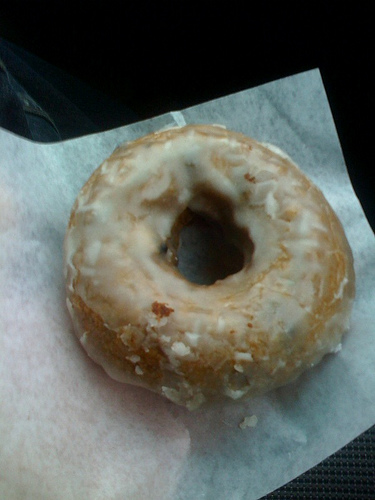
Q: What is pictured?
A: A donut.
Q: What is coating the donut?
A: Frosting.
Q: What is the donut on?
A: Wax paper.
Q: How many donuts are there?
A: 1.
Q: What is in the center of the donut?
A: A hole.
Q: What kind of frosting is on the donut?
A: A glaze.